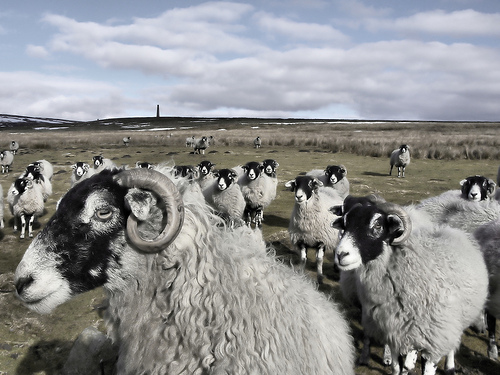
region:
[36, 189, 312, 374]
A large grey and black ram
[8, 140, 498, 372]
About twenty sheep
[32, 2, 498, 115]
Cloudy sky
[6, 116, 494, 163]
Barren field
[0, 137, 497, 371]
Many free range sheep and ram.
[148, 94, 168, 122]
Large chimney or grain silo in the distance.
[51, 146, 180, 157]
Sheep feces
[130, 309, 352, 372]
Grey colored wool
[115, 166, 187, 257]
Large horn of a ram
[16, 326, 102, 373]
Shadow of a sheep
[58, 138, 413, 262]
this are mountain sheeps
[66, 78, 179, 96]
the weather looks cloudy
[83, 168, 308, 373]
this sheeps have grey fur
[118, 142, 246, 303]
they also have horns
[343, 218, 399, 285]
they have white and black regions on their faces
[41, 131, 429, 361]
what a lovely photo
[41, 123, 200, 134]
the vegetation is brown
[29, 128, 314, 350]
this is an outdoor photo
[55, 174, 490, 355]
i love sheeps indeed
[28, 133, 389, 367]
what a good picture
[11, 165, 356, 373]
Sheep with a curly coat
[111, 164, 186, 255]
curled horn on a sheep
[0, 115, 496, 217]
a very flat landscape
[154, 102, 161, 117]
tall structure in the distance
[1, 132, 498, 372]
herd of sheep all headed towards the camera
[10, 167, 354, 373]
sheep with a black face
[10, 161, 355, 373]
sheep with pale grey curly coat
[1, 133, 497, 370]
a herd of sheep that are all the same breed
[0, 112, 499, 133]
snow on the ground in the distance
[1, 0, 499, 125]
the sky is pale blue and cloudy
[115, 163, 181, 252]
the horn on a goat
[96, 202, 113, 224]
the eye of a goat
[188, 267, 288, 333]
long wool on a goat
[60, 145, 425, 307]
a herd of standing goats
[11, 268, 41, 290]
a goat's nose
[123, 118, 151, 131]
snow on a hill side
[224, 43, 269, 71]
clouds in the sky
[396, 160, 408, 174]
the front legs of a goat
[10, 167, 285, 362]
a goat with horns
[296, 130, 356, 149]
tall grass in a field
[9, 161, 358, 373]
Sheep nearest to the camera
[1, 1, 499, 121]
Cloudy sky in the background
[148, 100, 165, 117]
Tower on the horizon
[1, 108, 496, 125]
The horizon line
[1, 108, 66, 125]
The highest portion of the horizon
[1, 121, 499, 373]
Grass field the sheep are standing in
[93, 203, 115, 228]
Eye of the closest sheep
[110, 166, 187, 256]
Horn of the closest sheep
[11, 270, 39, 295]
Nose of the closest sheep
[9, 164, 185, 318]
Head of the closest sheep